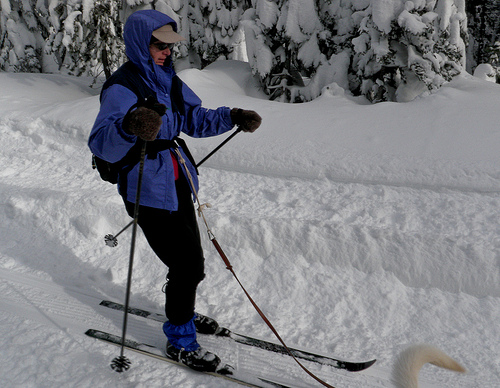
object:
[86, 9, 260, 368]
skier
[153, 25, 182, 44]
hat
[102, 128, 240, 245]
ski pole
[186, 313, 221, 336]
left boot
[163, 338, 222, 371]
right boot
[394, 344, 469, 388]
dog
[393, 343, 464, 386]
tail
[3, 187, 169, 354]
shadow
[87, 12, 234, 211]
jacket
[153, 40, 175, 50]
sunglasses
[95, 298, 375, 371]
ski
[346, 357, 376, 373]
tip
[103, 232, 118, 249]
bottom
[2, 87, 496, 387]
snow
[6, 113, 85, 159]
tracks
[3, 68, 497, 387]
ground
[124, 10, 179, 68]
hood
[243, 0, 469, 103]
tree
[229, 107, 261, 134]
glove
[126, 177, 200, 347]
pants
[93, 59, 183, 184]
backpack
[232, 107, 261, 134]
hand